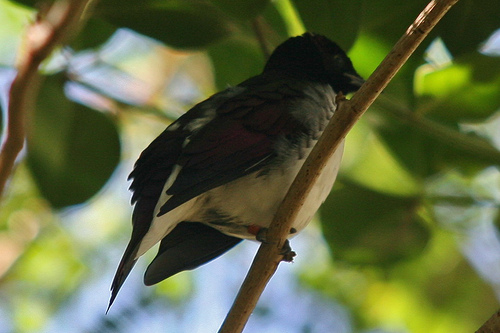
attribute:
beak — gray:
[346, 74, 362, 95]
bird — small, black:
[121, 31, 372, 295]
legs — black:
[258, 221, 303, 267]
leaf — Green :
[24, 70, 120, 210]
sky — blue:
[193, 234, 346, 331]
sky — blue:
[55, 300, 98, 328]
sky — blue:
[463, 235, 498, 258]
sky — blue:
[118, 33, 138, 49]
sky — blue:
[0, 308, 10, 329]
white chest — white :
[305, 123, 344, 203]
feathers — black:
[294, 42, 306, 59]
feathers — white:
[151, 124, 258, 211]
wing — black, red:
[156, 103, 308, 217]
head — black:
[266, 26, 366, 92]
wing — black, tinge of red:
[90, 82, 248, 306]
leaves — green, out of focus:
[353, 108, 496, 323]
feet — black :
[253, 229, 295, 261]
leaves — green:
[0, 1, 499, 330]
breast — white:
[266, 101, 346, 234]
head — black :
[267, 24, 371, 102]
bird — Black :
[108, 25, 366, 315]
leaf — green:
[402, 44, 498, 116]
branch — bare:
[220, 0, 450, 330]